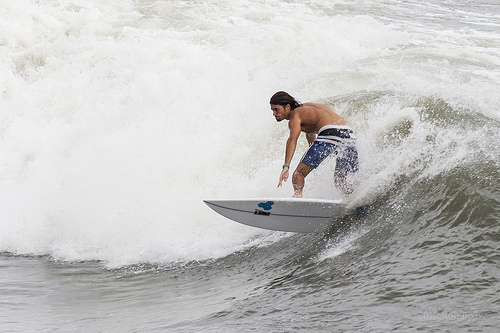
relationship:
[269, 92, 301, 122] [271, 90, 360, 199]
head on surfer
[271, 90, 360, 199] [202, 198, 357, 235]
surfer on top of surf board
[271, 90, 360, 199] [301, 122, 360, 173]
surfer wearing shorts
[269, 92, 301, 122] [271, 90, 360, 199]
head on top of surfer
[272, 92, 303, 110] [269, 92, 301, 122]
hair on top of head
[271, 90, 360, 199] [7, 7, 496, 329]
surfer in water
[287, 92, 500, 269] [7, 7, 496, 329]
wave forming in water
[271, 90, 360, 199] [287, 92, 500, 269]
surfer riding a wave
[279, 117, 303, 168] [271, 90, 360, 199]
arm on surfer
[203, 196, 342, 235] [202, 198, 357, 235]
tip of surf board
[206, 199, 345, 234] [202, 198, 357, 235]
bottom of surf board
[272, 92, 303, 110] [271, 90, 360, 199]
hair on top of surfer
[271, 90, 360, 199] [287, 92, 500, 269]
surfer enjoying wave